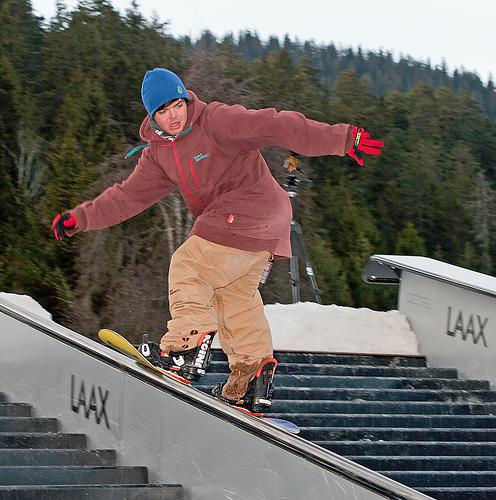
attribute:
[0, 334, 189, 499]
stairs are gray — grey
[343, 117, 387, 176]
gloves are orange — black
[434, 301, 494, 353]
word laax — black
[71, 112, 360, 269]
brown coat — red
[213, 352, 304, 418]
snowboarding boot — black